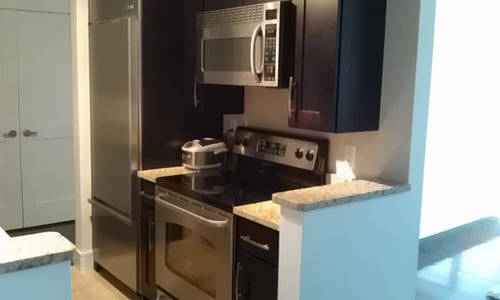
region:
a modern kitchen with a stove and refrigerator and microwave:
[0, 0, 495, 296]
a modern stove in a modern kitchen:
[145, 105, 325, 290]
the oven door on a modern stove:
[140, 180, 245, 295]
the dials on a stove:
[225, 122, 331, 172]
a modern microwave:
[188, 5, 296, 97]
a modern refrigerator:
[80, 12, 156, 293]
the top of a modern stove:
[160, 157, 290, 209]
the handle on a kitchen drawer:
[235, 227, 275, 255]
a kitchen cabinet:
[277, 0, 395, 142]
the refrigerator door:
[78, 17, 136, 222]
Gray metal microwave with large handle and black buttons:
[185, 2, 295, 89]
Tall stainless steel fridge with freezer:
[76, 5, 146, 290]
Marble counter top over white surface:
[274, 168, 400, 227]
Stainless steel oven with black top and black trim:
[137, 115, 311, 295]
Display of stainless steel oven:
[260, 137, 288, 158]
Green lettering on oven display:
[262, 137, 284, 154]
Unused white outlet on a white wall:
[340, 137, 362, 172]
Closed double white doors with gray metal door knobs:
[0, 23, 78, 225]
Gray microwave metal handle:
[240, 19, 270, 86]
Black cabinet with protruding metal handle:
[278, 6, 373, 134]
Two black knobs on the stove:
[292, 144, 314, 162]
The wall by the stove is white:
[336, 222, 390, 281]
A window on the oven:
[163, 220, 215, 290]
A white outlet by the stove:
[346, 144, 356, 167]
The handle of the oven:
[152, 193, 222, 228]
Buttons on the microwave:
[264, 23, 276, 86]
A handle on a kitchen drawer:
[233, 231, 271, 251]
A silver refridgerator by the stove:
[86, 2, 140, 292]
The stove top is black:
[180, 177, 297, 189]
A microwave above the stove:
[195, 3, 277, 87]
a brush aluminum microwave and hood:
[196, 5, 288, 90]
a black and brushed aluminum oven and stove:
[154, 127, 328, 299]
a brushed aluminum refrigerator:
[85, 0, 238, 295]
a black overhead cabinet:
[286, 2, 381, 133]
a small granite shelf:
[271, 177, 412, 212]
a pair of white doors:
[1, 0, 75, 230]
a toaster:
[180, 135, 225, 167]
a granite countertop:
[230, 200, 282, 229]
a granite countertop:
[135, 164, 205, 183]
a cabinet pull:
[285, 75, 296, 123]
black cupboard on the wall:
[291, 1, 376, 133]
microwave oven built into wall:
[195, 5, 288, 95]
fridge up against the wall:
[87, 3, 149, 289]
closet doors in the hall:
[1, 8, 78, 255]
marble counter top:
[280, 180, 397, 202]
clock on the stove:
[257, 133, 288, 160]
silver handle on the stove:
[152, 192, 237, 234]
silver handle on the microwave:
[252, 25, 266, 84]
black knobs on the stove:
[295, 148, 315, 162]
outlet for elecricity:
[222, 114, 237, 141]